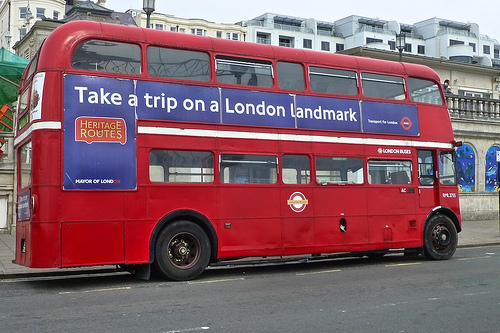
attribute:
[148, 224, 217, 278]
tire — black, back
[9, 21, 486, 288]
bus — red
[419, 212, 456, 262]
wheel — black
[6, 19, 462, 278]
double-decker bus — empty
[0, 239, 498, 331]
street — paved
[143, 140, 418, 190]
windows — rectangular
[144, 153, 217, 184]
window — bottom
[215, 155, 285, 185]
window — bottom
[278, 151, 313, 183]
window — bottom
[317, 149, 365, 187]
window — bottom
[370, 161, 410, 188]
window — bottom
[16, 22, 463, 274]
bus — Red, double decker, parked